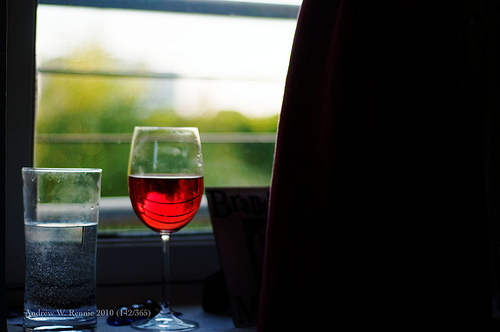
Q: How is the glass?
A: Half full.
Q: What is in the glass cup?
A: Water.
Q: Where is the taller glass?
A: On the right.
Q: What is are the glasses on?
A: A dark table.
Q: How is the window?
A: Closed.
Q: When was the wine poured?
A: Before the photo.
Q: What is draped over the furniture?
A: A red blanket.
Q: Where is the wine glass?
A: Next to the water glass.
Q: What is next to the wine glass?
A: A glass of water.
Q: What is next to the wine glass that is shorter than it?
A: Glass of water.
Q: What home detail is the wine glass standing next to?
A: Window.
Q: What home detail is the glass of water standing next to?
A: Window.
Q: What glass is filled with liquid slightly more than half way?
A: Glass of water.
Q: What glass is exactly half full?
A: Wine glass.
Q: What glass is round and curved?
A: Wine glass.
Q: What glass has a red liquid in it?
A: Wine glass.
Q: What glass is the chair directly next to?
A: Wine glass.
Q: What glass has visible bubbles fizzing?
A: Glass of water.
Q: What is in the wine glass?
A: Red wine.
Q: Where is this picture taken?
A: A train.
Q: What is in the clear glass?
A: Water.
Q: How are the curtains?
A: Opened.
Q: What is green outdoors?
A: Trees.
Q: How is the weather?
A: Clear.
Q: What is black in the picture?
A: Curtains.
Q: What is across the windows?
A: Bars.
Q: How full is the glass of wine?
A: It is half full.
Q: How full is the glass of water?
A: Almost full.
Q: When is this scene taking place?
A: Day time.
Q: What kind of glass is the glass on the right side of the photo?
A: Wine glass.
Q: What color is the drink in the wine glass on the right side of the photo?
A: Red.